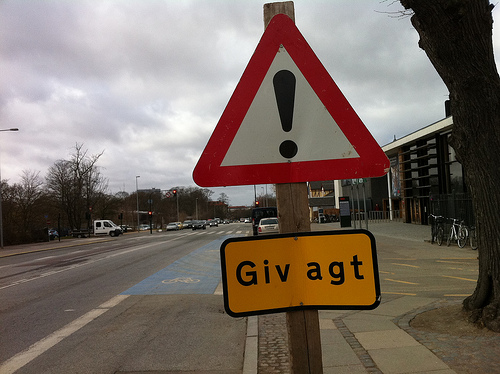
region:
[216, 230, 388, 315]
yellow and black sign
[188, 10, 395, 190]
red and white sign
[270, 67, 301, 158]
black exclamation sign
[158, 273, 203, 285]
image of a bike on the road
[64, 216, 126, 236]
white flat bed truck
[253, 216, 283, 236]
white car on the side of the road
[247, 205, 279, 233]
black van on the side of the road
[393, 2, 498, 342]
tree trunk on a sidewalk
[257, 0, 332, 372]
wooden sign post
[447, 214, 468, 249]
white bike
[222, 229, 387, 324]
Yellow and black sign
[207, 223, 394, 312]
Giv agt sign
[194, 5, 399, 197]
Red, white and black sign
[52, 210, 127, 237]
Truck on a road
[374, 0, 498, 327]
Tree on a sidewalk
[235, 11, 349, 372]
Wood post with signs on it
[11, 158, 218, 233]
Bare trees by a road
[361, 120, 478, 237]
Glass windows on a building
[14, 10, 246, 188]
White clouds in the sky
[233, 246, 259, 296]
Black letter on yellow sign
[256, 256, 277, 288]
Black letter on yellow sign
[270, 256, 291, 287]
Black letter on yellow sign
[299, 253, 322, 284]
Black letter on yellow sign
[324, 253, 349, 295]
Black letter on yellow sign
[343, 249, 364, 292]
Black letter on yellow sign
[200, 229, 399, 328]
black and yellow sign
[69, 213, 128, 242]
White truck on pavement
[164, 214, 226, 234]
Several cars on pavement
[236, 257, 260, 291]
black letter on sign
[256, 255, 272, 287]
black letter on sign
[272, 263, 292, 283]
black letter on sign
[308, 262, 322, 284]
black letter on sign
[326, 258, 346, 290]
black letter on sign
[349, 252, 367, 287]
black letter on sign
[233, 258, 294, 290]
black letters on sign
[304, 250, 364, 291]
black letters on sign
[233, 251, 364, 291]
black letters on sign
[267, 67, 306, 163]
black symbol on sign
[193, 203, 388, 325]
black and yellow sign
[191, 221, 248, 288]
corner of the sign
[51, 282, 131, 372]
white line on ground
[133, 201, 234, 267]
cars on the street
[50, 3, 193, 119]
clouds above the land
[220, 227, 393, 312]
yellow and black street sign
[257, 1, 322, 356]
wood post holding signs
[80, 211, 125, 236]
white truck on street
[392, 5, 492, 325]
tree trunk on sidewalk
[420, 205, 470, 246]
bikes along sidewalk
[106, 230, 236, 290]
blue paint on the road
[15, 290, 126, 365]
white line on the road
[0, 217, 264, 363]
street with lots of cars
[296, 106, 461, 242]
building in the back